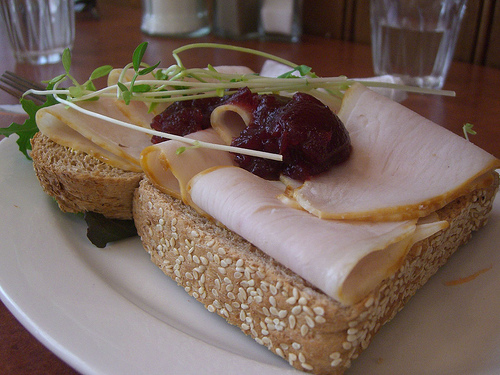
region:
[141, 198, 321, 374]
Sesame seeds on bread crust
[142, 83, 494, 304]
Three pieces of turkey lunchmeat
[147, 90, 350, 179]
Berry preserves on top of lunchmeat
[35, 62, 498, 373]
Two halves of a lunch meat sandwich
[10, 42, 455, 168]
Greens laid on a sandwich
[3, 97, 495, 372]
Sandwich on a round white plate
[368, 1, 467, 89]
Half full glass of water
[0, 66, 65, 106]
Pitch end of a silver fork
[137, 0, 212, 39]
Bottom of a glass sugar shaker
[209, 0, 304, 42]
Glass salt and pepper shakers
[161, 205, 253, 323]
bread with seeds on the sides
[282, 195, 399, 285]
turkey sandwich meat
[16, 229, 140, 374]
a round white plate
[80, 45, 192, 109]
green leaves on a stem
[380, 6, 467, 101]
a clear glass with water in it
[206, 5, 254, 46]
a container with pepper in it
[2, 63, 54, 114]
a fork laying on a table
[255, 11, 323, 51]
a container with salt in it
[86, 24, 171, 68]
a brown dining table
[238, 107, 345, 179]
purple sauce on top of a sandwich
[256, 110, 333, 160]
Purple sauce on top of white meat.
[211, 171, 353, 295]
Piece of white meat on bread.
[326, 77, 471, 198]
Piece of white meat on bread.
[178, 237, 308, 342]
White seeds on bread.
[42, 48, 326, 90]
Green leafy garnish on top of sandwich.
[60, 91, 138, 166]
Piece of white meat on bread.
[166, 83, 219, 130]
Purple sauce on top of meat.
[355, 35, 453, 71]
Glass of water on table.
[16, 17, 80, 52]
Glass of water sitting on table.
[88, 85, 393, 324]
Food is sitting on white plate.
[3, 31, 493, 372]
sandwich on a white plate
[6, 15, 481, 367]
one piece of bread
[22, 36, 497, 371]
bread with seeds on it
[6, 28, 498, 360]
bread with meat on it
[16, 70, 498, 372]
bread with cranberry sauce on it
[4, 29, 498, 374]
sandwich with one piece of bread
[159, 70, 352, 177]
red cranberry sauce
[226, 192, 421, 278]
piece of meat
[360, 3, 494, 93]
cup with water in it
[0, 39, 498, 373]
cranberry and meat sandwich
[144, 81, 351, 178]
a dollop of cranberry sauce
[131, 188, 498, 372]
bread covered in sesame seeds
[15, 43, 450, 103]
a few bean sprouts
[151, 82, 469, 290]
sliced and folded deli turkey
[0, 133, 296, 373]
a white china plate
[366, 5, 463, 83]
a glass with water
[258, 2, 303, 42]
a glass salt shaker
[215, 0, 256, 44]
glass black pepper shaker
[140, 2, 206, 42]
a glass sugar container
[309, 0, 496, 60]
brown beadboard paneling